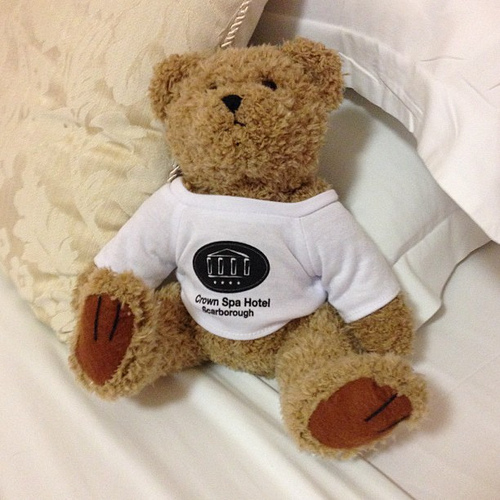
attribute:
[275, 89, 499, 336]
pillow — decorative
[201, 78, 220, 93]
eye — black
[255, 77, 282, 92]
eye — black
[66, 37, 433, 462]
doll — brown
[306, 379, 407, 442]
sole — brown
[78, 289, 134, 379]
sole — brown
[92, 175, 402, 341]
vest — white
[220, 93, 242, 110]
nose — sewn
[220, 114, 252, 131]
mouth — sewn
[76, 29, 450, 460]
bear — light brown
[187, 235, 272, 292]
picture — black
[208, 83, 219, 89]
eye — black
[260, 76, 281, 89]
eye — black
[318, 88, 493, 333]
pillow — white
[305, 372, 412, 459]
paddings — brown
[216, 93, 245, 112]
nose — black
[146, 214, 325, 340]
shirt — white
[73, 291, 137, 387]
bottom — brown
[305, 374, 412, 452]
bottom — brown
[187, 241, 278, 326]
logo — black, white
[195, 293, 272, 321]
lettering — black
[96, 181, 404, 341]
shirt — white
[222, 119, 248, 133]
mouth — black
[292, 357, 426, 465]
feet — dark brown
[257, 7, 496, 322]
pillow — white